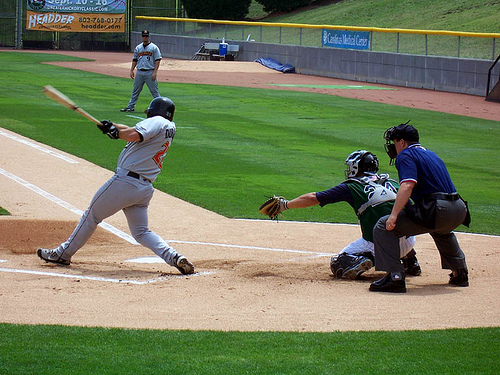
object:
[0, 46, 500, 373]
field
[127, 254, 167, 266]
plate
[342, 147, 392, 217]
protective gear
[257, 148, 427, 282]
man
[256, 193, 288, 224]
glove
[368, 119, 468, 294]
umpire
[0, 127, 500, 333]
pitch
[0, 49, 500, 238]
grass